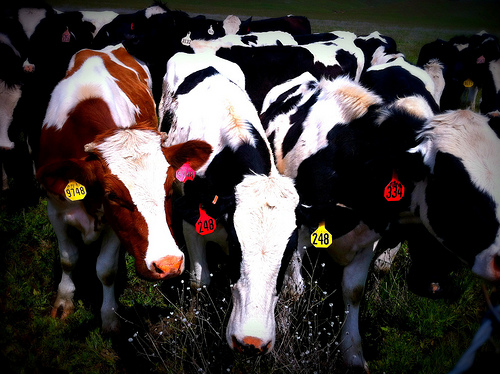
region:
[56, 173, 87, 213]
tag attached to cow's ear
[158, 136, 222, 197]
tag attached to cow's ear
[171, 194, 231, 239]
tag attached to cow's ear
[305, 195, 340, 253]
tag attached to cow's ear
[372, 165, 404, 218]
tag attached to cow's ear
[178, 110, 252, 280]
black and white cow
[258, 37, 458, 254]
black and white cow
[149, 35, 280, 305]
black and white cow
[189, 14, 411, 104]
black and white cow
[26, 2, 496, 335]
cows standing together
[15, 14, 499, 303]
black and white cows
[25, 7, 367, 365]
a brown and white cow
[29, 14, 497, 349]
cows that are tagged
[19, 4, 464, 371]
cows with tags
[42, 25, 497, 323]
cows with tags in their ear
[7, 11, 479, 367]
cows with yellow tags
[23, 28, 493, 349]
cows with red tags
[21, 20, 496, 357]
cows standing on the grass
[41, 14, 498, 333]
cows standing in a field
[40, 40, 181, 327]
brown and white cow standing on grass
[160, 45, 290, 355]
Black and white cow standing on grass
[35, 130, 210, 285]
Brown and white cow with a number 9748 ear tag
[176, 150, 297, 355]
Black and white cow with a number 248 ear tag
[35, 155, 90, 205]
Yellow ear tag displaying the number 9748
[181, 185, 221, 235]
Red ear tag displaying the number 248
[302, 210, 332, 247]
Yellow ear tag displaying the number 248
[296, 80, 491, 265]
Black and white cow with a red ear tag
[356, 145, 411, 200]
Red ear tag displaying the number 334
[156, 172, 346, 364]
Black and white cow snacking on a flowered weed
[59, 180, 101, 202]
yellow number tag on cow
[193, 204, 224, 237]
red number tag on cow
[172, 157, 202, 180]
red number tag on cow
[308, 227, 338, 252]
yellow number tag on cow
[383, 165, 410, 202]
red number tag on cow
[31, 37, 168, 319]
white and brown cow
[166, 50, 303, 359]
white and black cow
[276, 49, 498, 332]
white and black cow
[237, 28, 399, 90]
white and black cow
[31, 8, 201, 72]
white and black cow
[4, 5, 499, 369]
a herd of cows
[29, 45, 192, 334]
brown and white cow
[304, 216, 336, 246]
yellow tag in the ear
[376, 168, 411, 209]
red tag in the ear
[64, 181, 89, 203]
black numbers on the yellow tag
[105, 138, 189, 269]
white stripe on the face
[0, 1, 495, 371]
cows standing in the grass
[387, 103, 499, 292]
head turned to the side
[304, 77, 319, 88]
small black spot